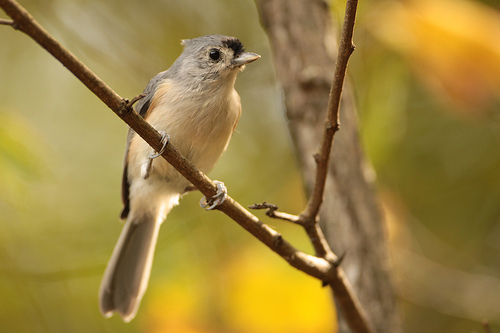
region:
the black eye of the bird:
[206, 47, 222, 62]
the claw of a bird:
[145, 127, 170, 161]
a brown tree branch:
[0, 0, 380, 332]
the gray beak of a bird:
[230, 47, 262, 68]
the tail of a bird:
[93, 207, 168, 324]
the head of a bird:
[166, 31, 264, 93]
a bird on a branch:
[97, 32, 264, 324]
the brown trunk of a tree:
[255, 0, 412, 332]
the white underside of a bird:
[125, 72, 242, 221]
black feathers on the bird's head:
[221, 35, 244, 55]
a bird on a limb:
[94, 27, 264, 327]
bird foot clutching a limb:
[193, 169, 233, 217]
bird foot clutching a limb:
[150, 129, 175, 160]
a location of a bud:
[317, 115, 343, 135]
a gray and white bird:
[93, 33, 265, 322]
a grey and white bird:
[80, 32, 265, 321]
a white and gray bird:
[86, 27, 262, 323]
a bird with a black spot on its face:
[158, 32, 259, 94]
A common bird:
[91, 37, 223, 321]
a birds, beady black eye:
[200, 42, 233, 67]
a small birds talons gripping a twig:
[145, 124, 177, 166]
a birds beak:
[234, 43, 261, 75]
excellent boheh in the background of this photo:
[82, 17, 147, 62]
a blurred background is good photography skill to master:
[375, 14, 480, 150]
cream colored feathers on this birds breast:
[174, 103, 216, 148]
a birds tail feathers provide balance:
[94, 234, 174, 321]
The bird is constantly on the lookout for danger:
[168, 22, 255, 107]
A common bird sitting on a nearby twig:
[77, 24, 259, 322]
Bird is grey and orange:
[74, 22, 271, 329]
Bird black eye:
[198, 41, 228, 69]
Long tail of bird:
[90, 206, 166, 326]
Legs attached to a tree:
[138, 120, 234, 216]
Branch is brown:
[275, 0, 382, 330]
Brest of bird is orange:
[160, 86, 240, 172]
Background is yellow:
[162, 245, 332, 330]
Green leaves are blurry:
[373, 98, 488, 243]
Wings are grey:
[105, 65, 150, 200]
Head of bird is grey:
[154, 20, 267, 88]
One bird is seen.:
[110, 38, 270, 248]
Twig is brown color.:
[31, 35, 176, 200]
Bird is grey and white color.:
[110, 45, 307, 295]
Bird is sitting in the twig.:
[131, 71, 251, 236]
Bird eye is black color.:
[207, 46, 218, 58]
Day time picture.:
[10, 20, 487, 315]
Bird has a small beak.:
[230, 50, 260, 61]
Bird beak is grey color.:
[235, 45, 261, 73]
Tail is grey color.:
[91, 219, 176, 321]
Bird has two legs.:
[133, 124, 243, 216]